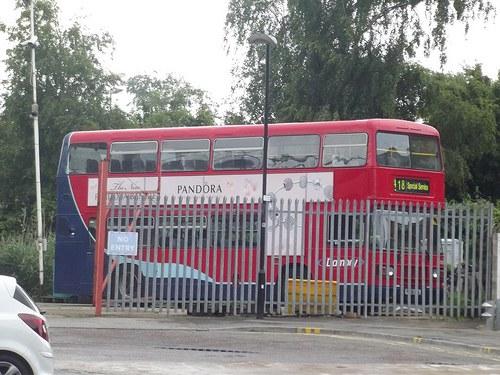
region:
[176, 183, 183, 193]
black letter on bus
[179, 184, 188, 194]
black letter on bus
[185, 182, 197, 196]
black letter on bus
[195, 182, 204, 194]
black letter on bus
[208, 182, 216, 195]
black letter on bus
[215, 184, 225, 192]
black letter on bus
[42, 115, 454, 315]
red and blue double decker bus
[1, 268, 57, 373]
back end of small white car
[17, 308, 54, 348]
red tail light of small car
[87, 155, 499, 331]
gray fence near bus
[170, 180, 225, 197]
PANDORA sign on side of bus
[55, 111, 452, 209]
top deck of bus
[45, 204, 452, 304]
bottom deck of bus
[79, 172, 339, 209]
white sign on side of bus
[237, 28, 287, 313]
tall black electric light pole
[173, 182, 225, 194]
Pandora business logo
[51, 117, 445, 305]
red white and blue bus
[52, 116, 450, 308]
a double decker bus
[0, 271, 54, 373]
white compact car's rear end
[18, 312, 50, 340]
tail light on a white car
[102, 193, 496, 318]
metal spiked fence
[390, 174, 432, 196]
sign on front of bus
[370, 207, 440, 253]
bus front windshield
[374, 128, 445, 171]
bus front windshield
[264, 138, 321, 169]
side window on a bus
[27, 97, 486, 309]
this is a bus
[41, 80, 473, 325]
the bus is red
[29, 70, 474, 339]
the bus is a double decker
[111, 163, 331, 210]
advertisement on side of bus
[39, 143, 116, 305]
blue trim on bus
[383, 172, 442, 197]
digital sign on bus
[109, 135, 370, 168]
row of top windows on bus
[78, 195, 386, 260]
row of bottom windows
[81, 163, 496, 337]
this is a fence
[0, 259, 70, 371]
the back of a car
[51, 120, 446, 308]
A red, white and blue double decker bus.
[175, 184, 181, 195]
Black P in PANDORA.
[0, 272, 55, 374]
The back of a white car.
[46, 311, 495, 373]
A grey road.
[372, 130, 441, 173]
Top two windshields of a bus.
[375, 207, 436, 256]
Bottom windshield of a bus.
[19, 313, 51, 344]
Red tail light on the back of a car.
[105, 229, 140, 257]
Blue and white no entry sign.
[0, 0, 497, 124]
A white sky.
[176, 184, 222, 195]
Word PANDORA on a bus.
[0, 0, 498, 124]
light in daytime sky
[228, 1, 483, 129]
green leaves on trees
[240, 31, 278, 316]
light on top of pole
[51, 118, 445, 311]
side of double decker bus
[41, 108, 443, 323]
Red and blue double decker bus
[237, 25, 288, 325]
A black street lamp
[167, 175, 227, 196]
"PANDORA" written on white sign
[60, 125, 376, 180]
Side windows of a bus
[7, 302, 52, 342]
A red rear light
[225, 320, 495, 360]
The curb of a sidewalk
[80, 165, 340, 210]
A white sign on the bus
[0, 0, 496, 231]
Green leaves on the trees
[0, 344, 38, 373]
A black rubber tire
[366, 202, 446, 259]
Front window of a bus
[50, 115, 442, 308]
large red and blue bus parked behind a silver fence